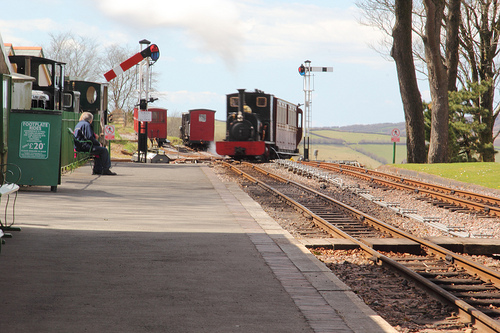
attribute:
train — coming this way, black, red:
[219, 89, 304, 164]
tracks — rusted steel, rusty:
[215, 154, 500, 332]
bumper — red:
[215, 141, 265, 156]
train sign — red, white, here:
[105, 42, 162, 81]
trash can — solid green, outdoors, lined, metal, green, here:
[7, 106, 63, 189]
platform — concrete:
[0, 160, 398, 331]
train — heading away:
[180, 107, 215, 149]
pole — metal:
[137, 39, 153, 163]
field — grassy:
[384, 162, 499, 190]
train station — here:
[0, 53, 396, 331]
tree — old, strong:
[391, 1, 428, 163]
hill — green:
[299, 127, 409, 167]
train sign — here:
[295, 63, 334, 75]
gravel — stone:
[218, 156, 499, 332]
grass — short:
[388, 162, 499, 191]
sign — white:
[138, 110, 153, 123]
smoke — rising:
[109, 10, 246, 87]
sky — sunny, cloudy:
[1, 1, 499, 128]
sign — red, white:
[390, 126, 402, 142]